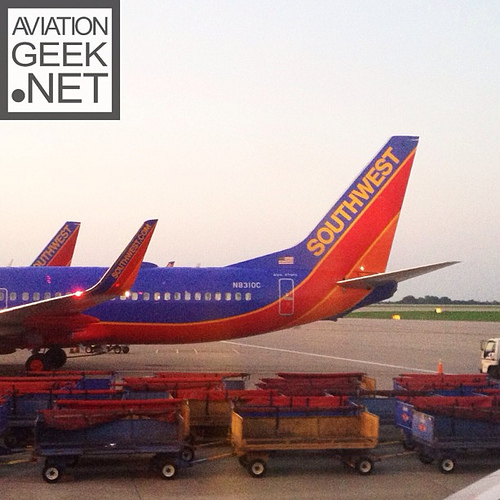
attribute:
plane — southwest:
[0, 134, 456, 367]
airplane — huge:
[0, 125, 469, 367]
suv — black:
[29, 412, 203, 483]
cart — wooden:
[230, 405, 385, 459]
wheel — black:
[247, 458, 269, 480]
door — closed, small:
[271, 272, 300, 320]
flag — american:
[274, 251, 300, 269]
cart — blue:
[408, 402, 498, 477]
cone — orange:
[434, 356, 446, 379]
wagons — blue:
[2, 371, 499, 470]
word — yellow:
[304, 145, 404, 258]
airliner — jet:
[0, 134, 464, 375]